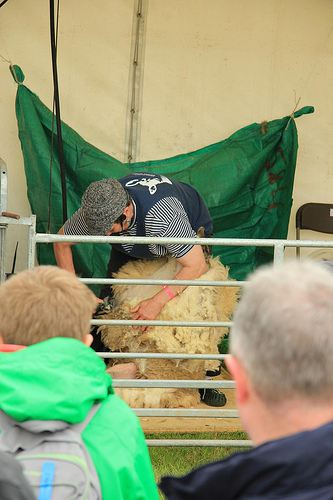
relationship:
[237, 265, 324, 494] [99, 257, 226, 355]
man watching sheep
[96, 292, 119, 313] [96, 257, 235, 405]
sheep shears shearing sheep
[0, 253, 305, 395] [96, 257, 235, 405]
people watching sheep